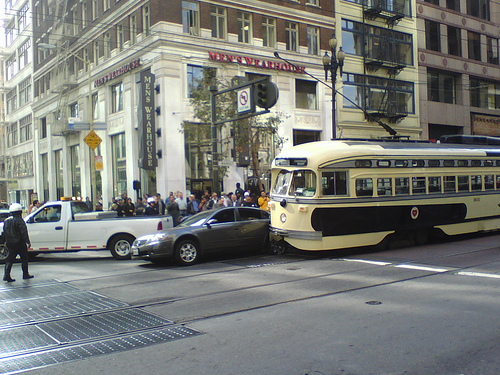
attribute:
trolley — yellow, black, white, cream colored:
[271, 138, 496, 253]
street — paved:
[2, 235, 500, 374]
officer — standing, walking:
[3, 203, 37, 285]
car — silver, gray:
[134, 204, 293, 265]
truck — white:
[4, 201, 174, 263]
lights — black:
[252, 82, 273, 111]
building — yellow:
[337, 2, 421, 141]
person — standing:
[166, 197, 179, 230]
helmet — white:
[7, 203, 23, 214]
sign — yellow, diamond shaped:
[82, 130, 105, 153]